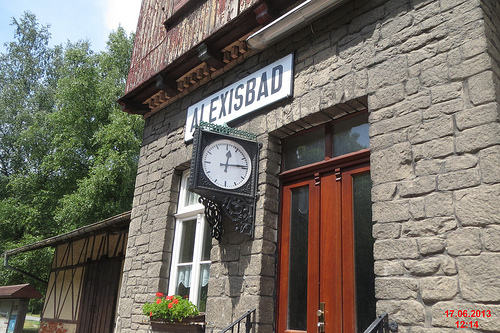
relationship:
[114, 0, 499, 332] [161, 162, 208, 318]
building has window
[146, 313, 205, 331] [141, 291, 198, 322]
planter with flowers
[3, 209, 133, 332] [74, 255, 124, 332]
building has door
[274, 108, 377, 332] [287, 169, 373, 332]
door has windows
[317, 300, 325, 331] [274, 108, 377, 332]
doorknob on door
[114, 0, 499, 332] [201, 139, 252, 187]
building has clock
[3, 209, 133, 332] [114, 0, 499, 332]
building beside building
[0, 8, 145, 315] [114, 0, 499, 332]
trees behind building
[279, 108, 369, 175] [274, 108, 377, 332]
windows above door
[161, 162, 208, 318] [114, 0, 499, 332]
window in building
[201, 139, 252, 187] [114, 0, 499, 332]
clock on building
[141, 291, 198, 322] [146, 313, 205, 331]
flowers in planter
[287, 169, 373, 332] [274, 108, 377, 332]
windows in door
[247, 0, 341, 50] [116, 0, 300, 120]
light under eaves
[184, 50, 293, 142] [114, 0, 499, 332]
sign on building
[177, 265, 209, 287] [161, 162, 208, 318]
curtains in window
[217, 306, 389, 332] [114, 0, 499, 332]
railings on building